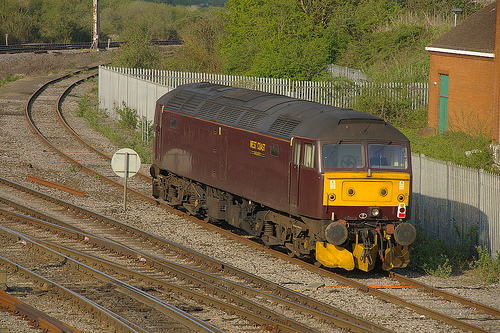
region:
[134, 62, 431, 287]
burgundy and yellow train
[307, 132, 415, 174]
two windows on the front of the train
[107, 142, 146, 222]
sign in between railroad tracks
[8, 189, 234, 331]
railroad tracks lined with gravel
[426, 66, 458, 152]
green door on the bulding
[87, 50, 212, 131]
wooden fence behind the train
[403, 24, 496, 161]
brown building with a dark roof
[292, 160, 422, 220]
yellow stripe on the front of the train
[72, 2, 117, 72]
metal pole in the background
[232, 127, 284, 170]
yellow writing on the side of the train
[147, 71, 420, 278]
a maroon and yellow train engine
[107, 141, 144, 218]
the back of a sign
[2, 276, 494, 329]
various train tracks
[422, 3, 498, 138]
brown building with a grey roof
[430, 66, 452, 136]
a green door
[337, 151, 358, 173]
steering wheel of a train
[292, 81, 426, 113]
white picket fence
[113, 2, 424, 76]
brown and green trees and shrubs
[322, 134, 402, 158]
windshield wipers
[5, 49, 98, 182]
a bend in a train track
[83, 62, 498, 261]
There's a fence surrounding the structure.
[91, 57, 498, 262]
The fence is made from wood.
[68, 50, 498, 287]
The fence is painted white.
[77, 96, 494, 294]
Weeds are growing along outside of fence.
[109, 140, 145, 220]
Round sign on a post.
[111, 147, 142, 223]
Round sign in between train tracks.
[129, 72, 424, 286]
Train is sitting on the tracks.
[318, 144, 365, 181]
The train has no driver.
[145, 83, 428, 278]
The train is brown.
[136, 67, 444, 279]
Train on tracks closest to fence.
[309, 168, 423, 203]
Yellow panel on train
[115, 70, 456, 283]
One train car on track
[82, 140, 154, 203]
Sign in the middle of the tracks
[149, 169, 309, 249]
Wheels and gears under the car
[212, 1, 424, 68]
Green trees to the side of the tracks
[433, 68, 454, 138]
Thin green window on building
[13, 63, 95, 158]
Curve in the train tracks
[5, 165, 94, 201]
Piece of wood on the ground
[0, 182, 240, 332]
Three sets of tracks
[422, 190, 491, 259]
Shadow of car on fence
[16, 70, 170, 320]
lot of five train tracks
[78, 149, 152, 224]
round rail road sign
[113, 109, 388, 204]
burgundy train car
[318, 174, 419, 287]
yellow trim on burgundy train car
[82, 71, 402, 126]
white wooden picket fence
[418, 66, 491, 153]
dark green door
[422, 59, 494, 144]
brown utility building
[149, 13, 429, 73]
large green bushes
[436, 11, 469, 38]
silver exhaust vent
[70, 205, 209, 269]
several wooden railroad ties